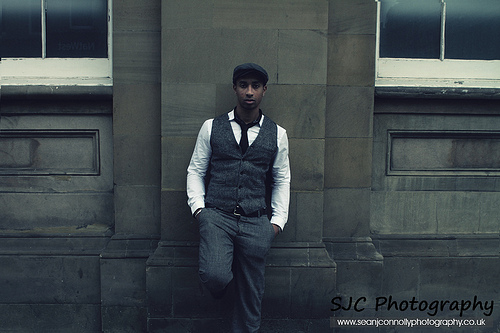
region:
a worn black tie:
[230, 118, 259, 150]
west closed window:
[1, 0, 111, 87]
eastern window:
[374, 0, 497, 85]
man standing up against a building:
[185, 61, 289, 331]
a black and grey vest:
[207, 110, 280, 215]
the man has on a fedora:
[232, 61, 267, 83]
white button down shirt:
[184, 108, 289, 231]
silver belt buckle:
[231, 204, 241, 217]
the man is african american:
[230, 62, 268, 110]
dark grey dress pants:
[196, 205, 274, 332]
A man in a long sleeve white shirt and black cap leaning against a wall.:
[186, 62, 292, 332]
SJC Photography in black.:
[328, 294, 494, 317]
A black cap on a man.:
[231, 62, 270, 86]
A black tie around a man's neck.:
[233, 110, 263, 152]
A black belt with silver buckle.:
[206, 200, 270, 217]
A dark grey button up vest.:
[204, 112, 278, 214]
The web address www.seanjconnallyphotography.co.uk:
[334, 318, 487, 328]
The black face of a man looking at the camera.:
[234, 76, 264, 106]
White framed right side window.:
[376, 0, 499, 89]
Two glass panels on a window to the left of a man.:
[1, 1, 109, 61]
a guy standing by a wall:
[173, 44, 328, 331]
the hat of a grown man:
[237, 57, 273, 84]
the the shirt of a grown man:
[181, 109, 306, 231]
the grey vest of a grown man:
[205, 113, 304, 228]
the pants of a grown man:
[183, 203, 286, 317]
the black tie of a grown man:
[228, 113, 258, 149]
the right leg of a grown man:
[186, 220, 228, 293]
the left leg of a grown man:
[233, 224, 283, 308]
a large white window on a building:
[360, 0, 497, 135]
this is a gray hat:
[233, 62, 267, 78]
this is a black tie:
[236, 117, 256, 147]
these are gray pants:
[199, 219, 271, 331]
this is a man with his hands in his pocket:
[188, 62, 288, 331]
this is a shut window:
[376, 0, 498, 86]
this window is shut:
[0, 0, 112, 85]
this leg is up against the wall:
[199, 207, 234, 293]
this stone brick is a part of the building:
[160, 0, 274, 29]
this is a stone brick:
[279, 30, 326, 87]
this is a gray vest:
[211, 120, 277, 210]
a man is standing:
[188, 62, 289, 332]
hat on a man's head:
[231, 59, 269, 79]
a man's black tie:
[233, 121, 255, 150]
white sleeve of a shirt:
[182, 118, 212, 211]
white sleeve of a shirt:
[272, 123, 291, 231]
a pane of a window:
[377, 1, 442, 57]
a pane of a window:
[445, 1, 499, 62]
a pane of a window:
[45, 1, 106, 60]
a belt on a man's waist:
[208, 201, 268, 218]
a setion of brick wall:
[111, 5, 370, 241]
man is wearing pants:
[196, 213, 279, 324]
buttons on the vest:
[234, 158, 247, 205]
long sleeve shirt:
[269, 176, 291, 214]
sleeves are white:
[273, 192, 287, 217]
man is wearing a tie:
[237, 125, 252, 156]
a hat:
[236, 63, 262, 74]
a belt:
[233, 204, 248, 215]